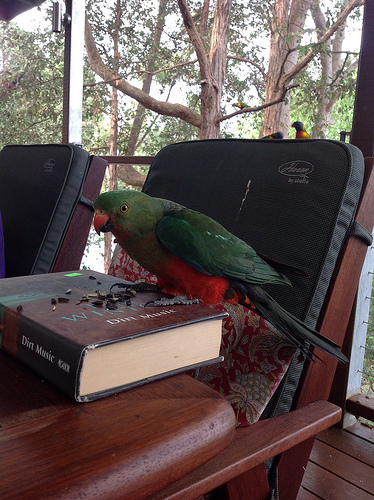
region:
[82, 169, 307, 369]
large bird sitting on book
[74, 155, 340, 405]
large bird standing on book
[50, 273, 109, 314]
bird seed on book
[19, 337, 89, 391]
white writing on side of book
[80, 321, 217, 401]
white pages of book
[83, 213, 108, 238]
orange beak of bird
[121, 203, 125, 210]
black eye of bird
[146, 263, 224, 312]
orange bottom of bird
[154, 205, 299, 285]
green wings of bird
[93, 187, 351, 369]
A parrot sitting on a book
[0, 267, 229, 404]
The large book on the table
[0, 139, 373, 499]
The brown wooden chair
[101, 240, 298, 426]
A patterned chair cushion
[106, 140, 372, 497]
The dark chair cushions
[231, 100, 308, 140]
The wild birds in the background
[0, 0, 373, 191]
The vegetation in the background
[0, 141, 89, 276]
The dark chair cushion on the left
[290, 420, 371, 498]
The wooden brown floor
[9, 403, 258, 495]
The chair is made of wood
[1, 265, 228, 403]
A book is on the chair table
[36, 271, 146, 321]
The food for the parrot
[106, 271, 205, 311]
The claws of the parrot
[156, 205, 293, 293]
The wings of the parrot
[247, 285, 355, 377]
The tail of the parrot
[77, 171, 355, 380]
The parrot is sitting on the book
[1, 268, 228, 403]
A thick book sitting on the wood.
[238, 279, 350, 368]
Black tail feathers of a bird.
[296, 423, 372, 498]
Brown wood floor.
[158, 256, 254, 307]
Orange underneath of a bird.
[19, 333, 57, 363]
Dirt Music on the side of a book.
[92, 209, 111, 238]
Red and black beak of a bird.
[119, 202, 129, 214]
Yellow and black eye of a bird.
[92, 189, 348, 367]
A green, red and black bird.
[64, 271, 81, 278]
Green sticker on a book.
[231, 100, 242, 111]
A bird up on a branch in a tree.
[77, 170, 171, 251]
head of a bird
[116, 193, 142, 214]
eye of a bird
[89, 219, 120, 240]
peck of a bird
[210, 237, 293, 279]
wing of a bird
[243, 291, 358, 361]
tail of a bird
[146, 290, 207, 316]
leg of a bird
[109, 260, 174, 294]
leg of a bird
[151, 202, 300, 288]
wing of a bird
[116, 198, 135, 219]
an eye of a bird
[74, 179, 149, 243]
a head of a bird